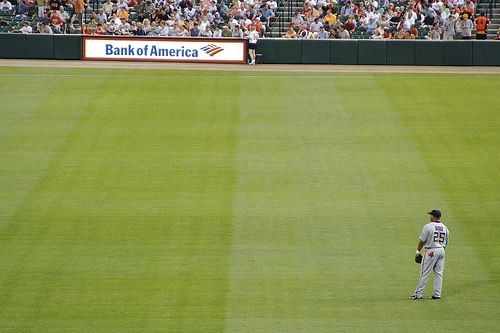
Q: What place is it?
A: It is a field.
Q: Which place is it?
A: It is a field.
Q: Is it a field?
A: Yes, it is a field.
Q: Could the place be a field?
A: Yes, it is a field.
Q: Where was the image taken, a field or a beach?
A: It was taken at a field.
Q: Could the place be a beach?
A: No, it is a field.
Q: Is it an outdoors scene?
A: Yes, it is outdoors.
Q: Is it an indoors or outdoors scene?
A: It is outdoors.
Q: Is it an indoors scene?
A: No, it is outdoors.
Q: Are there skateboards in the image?
A: No, there are no skateboards.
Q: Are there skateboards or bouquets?
A: No, there are no skateboards or bouquets.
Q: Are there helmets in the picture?
A: No, there are no helmets.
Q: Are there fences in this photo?
A: Yes, there is a fence.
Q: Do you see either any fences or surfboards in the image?
A: Yes, there is a fence.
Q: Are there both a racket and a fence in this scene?
A: No, there is a fence but no rackets.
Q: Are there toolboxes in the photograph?
A: No, there are no toolboxes.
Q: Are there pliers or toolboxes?
A: No, there are no toolboxes or pliers.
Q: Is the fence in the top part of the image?
A: Yes, the fence is in the top of the image.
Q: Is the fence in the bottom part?
A: No, the fence is in the top of the image.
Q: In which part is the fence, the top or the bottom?
A: The fence is in the top of the image.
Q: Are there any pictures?
A: No, there are no pictures.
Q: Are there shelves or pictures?
A: No, there are no pictures or shelves.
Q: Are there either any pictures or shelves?
A: No, there are no pictures or shelves.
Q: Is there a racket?
A: No, there are no rackets.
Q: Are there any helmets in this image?
A: No, there are no helmets.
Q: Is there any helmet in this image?
A: No, there are no helmets.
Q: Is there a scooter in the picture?
A: No, there are no scooters.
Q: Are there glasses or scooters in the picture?
A: No, there are no scooters or glasses.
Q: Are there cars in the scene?
A: No, there are no cars.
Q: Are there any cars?
A: No, there are no cars.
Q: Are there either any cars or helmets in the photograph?
A: No, there are no cars or helmets.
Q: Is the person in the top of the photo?
A: Yes, the person is in the top of the image.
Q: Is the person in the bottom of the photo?
A: No, the person is in the top of the image.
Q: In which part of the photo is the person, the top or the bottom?
A: The person is in the top of the image.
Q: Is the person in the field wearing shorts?
A: Yes, the person is wearing shorts.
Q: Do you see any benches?
A: No, there are no benches.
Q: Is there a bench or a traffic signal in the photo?
A: No, there are no benches or traffic lights.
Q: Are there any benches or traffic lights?
A: No, there are no benches or traffic lights.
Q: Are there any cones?
A: No, there are no cones.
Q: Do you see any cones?
A: No, there are no cones.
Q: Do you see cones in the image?
A: No, there are no cones.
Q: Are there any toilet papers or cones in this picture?
A: No, there are no cones or toilet papers.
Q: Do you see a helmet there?
A: No, there are no helmets.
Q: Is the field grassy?
A: Yes, the field is grassy.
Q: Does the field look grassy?
A: Yes, the field is grassy.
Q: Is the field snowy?
A: No, the field is grassy.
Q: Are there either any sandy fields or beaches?
A: No, there is a field but it is grassy.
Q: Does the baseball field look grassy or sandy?
A: The field is grassy.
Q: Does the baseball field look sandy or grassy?
A: The field is grassy.